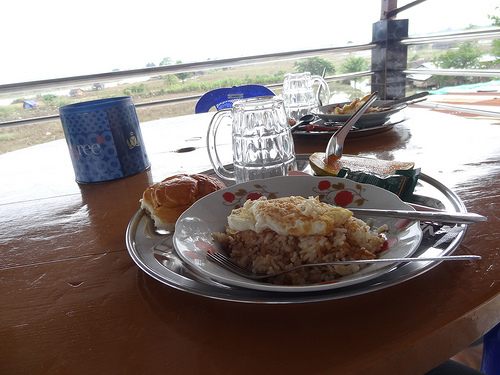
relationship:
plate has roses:
[171, 177, 423, 292] [221, 183, 274, 207]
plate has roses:
[171, 177, 423, 292] [316, 179, 366, 207]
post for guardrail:
[373, 19, 409, 102] [4, 27, 496, 127]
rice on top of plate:
[212, 219, 387, 287] [171, 177, 423, 292]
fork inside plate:
[207, 250, 482, 279] [171, 177, 423, 292]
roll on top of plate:
[140, 173, 227, 229] [168, 177, 423, 292]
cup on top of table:
[205, 96, 297, 184] [5, 91, 495, 369]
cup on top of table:
[282, 72, 328, 127] [5, 91, 495, 369]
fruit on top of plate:
[308, 152, 422, 199] [168, 177, 423, 292]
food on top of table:
[141, 171, 388, 286] [5, 91, 495, 369]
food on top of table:
[292, 99, 406, 132] [5, 91, 495, 369]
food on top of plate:
[141, 171, 388, 286] [171, 177, 423, 292]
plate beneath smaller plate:
[168, 177, 423, 292] [171, 177, 423, 292]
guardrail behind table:
[4, 27, 496, 127] [5, 91, 495, 369]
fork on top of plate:
[207, 250, 482, 279] [171, 177, 423, 292]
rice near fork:
[212, 219, 387, 287] [207, 250, 482, 279]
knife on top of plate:
[342, 206, 489, 225] [171, 177, 423, 292]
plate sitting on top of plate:
[171, 177, 423, 292] [168, 177, 423, 292]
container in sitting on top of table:
[60, 96, 152, 184] [5, 91, 495, 369]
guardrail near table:
[4, 27, 496, 127] [5, 91, 495, 369]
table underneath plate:
[5, 91, 495, 369] [171, 177, 423, 292]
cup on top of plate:
[205, 96, 297, 184] [168, 177, 423, 292]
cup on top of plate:
[282, 72, 328, 127] [286, 105, 410, 135]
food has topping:
[141, 171, 388, 286] [227, 196, 352, 235]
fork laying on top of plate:
[207, 250, 482, 279] [171, 177, 423, 292]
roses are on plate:
[221, 183, 274, 207] [171, 177, 423, 292]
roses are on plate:
[316, 179, 366, 207] [171, 177, 423, 292]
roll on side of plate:
[140, 173, 227, 229] [171, 177, 423, 292]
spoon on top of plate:
[326, 91, 380, 160] [168, 177, 423, 292]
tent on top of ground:
[20, 99, 37, 111] [5, 36, 497, 154]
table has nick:
[5, 91, 495, 369] [65, 278, 86, 289]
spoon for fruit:
[326, 91, 380, 160] [308, 152, 422, 199]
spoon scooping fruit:
[326, 91, 380, 160] [308, 152, 422, 199]